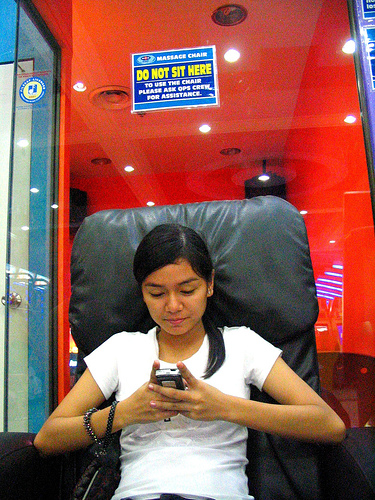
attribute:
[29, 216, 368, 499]
woman — sitting, asian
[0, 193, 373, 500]
chair — black, large, leather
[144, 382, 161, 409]
fingernails — polished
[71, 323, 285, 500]
shirt — short-sleeved, white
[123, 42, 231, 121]
sign — square, blue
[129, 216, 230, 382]
hair — black, long, dark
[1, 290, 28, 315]
doorknob — silver, chrome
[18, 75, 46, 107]
sticker — round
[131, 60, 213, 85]
do not sit here — yellow, yellow letters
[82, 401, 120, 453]
cord — black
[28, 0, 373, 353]
walls — red